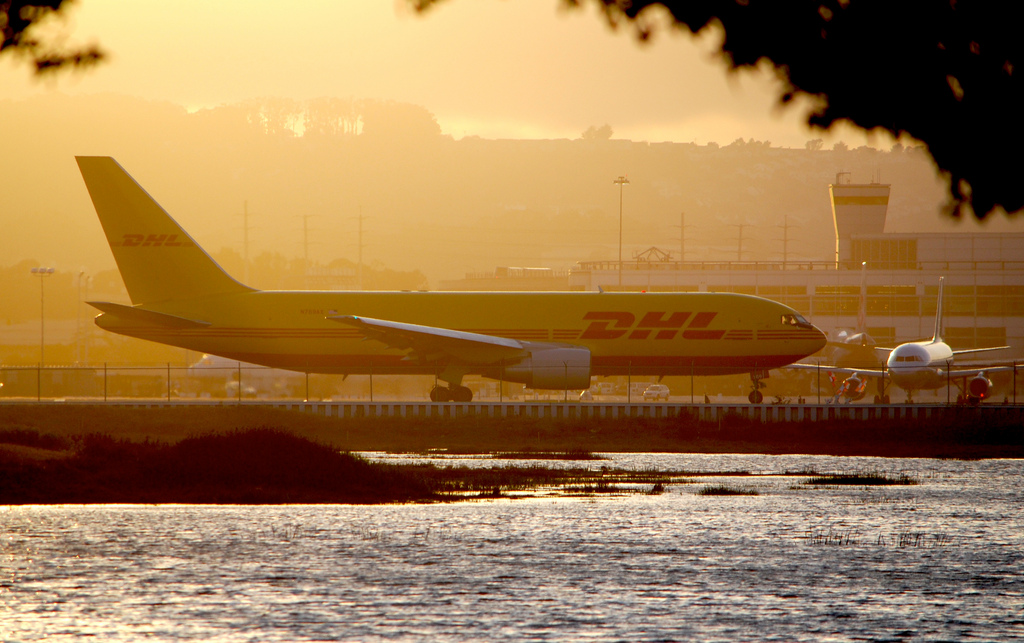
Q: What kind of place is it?
A: It is an airport.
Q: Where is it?
A: This is at the airport.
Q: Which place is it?
A: It is an airport.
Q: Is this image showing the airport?
A: Yes, it is showing the airport.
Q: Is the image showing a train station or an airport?
A: It is showing an airport.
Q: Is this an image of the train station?
A: No, the picture is showing the airport.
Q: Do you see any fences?
A: Yes, there is a fence.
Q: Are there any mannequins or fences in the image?
A: Yes, there is a fence.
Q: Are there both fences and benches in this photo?
A: No, there is a fence but no benches.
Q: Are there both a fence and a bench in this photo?
A: No, there is a fence but no benches.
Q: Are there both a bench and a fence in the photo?
A: No, there is a fence but no benches.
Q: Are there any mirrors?
A: No, there are no mirrors.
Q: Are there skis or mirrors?
A: No, there are no mirrors or skis.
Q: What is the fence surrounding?
A: The fence is surrounding the airport.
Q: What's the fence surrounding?
A: The fence is surrounding the airport.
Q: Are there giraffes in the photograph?
A: No, there are no giraffes.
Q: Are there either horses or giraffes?
A: No, there are no giraffes or horses.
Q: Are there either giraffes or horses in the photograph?
A: No, there are no giraffes or horses.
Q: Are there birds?
A: No, there are no birds.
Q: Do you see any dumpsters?
A: No, there are no dumpsters.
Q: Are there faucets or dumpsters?
A: No, there are no dumpsters or faucets.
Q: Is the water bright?
A: Yes, the water is bright.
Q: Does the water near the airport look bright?
A: Yes, the water is bright.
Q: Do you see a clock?
A: No, there are no clocks.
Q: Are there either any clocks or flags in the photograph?
A: No, there are no clocks or flags.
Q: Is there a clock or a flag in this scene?
A: No, there are no clocks or flags.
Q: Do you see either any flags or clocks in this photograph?
A: No, there are no clocks or flags.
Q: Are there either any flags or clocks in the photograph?
A: No, there are no clocks or flags.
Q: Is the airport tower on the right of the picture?
A: Yes, the tower is on the right of the image.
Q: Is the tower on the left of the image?
A: No, the tower is on the right of the image.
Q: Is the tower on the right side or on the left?
A: The tower is on the right of the image.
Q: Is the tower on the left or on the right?
A: The tower is on the right of the image.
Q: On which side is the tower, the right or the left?
A: The tower is on the right of the image.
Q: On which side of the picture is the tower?
A: The tower is on the right of the image.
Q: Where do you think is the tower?
A: The tower is at the airport.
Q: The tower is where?
A: The tower is at the airport.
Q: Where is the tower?
A: The tower is at the airport.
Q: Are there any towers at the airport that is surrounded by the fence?
A: Yes, there is a tower at the airport.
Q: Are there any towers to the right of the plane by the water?
A: Yes, there is a tower to the right of the plane.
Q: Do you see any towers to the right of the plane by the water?
A: Yes, there is a tower to the right of the plane.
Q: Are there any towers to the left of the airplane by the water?
A: No, the tower is to the right of the airplane.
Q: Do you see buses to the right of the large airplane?
A: No, there is a tower to the right of the airplane.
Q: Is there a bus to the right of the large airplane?
A: No, there is a tower to the right of the airplane.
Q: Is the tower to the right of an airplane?
A: Yes, the tower is to the right of an airplane.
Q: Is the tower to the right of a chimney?
A: No, the tower is to the right of an airplane.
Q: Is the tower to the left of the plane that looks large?
A: No, the tower is to the right of the plane.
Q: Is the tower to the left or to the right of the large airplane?
A: The tower is to the right of the airplane.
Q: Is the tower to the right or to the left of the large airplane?
A: The tower is to the right of the airplane.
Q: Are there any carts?
A: No, there are no carts.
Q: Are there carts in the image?
A: No, there are no carts.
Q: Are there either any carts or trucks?
A: No, there are no carts or trucks.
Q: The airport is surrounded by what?
A: The airport is surrounded by the fence.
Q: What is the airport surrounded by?
A: The airport is surrounded by the fence.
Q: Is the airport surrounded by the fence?
A: Yes, the airport is surrounded by the fence.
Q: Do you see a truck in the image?
A: No, there are no trucks.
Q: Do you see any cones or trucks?
A: No, there are no trucks or cones.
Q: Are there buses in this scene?
A: No, there are no buses.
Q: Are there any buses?
A: No, there are no buses.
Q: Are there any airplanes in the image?
A: Yes, there is an airplane.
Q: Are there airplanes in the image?
A: Yes, there is an airplane.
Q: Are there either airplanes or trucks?
A: Yes, there is an airplane.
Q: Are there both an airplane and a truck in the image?
A: No, there is an airplane but no trucks.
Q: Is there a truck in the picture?
A: No, there are no trucks.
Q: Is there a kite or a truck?
A: No, there are no trucks or kites.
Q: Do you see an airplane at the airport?
A: Yes, there is an airplane at the airport.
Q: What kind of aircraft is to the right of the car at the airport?
A: The aircraft is an airplane.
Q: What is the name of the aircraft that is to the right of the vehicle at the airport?
A: The aircraft is an airplane.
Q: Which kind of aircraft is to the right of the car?
A: The aircraft is an airplane.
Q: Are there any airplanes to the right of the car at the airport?
A: Yes, there is an airplane to the right of the car.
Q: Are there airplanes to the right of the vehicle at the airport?
A: Yes, there is an airplane to the right of the car.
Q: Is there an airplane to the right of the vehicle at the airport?
A: Yes, there is an airplane to the right of the car.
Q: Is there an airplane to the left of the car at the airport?
A: No, the airplane is to the right of the car.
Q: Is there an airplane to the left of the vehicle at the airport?
A: No, the airplane is to the right of the car.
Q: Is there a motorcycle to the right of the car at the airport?
A: No, there is an airplane to the right of the car.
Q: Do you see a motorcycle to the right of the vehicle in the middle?
A: No, there is an airplane to the right of the car.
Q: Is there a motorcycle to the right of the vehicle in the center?
A: No, there is an airplane to the right of the car.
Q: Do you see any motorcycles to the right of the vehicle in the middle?
A: No, there is an airplane to the right of the car.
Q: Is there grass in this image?
A: Yes, there is grass.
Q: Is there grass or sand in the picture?
A: Yes, there is grass.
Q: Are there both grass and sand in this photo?
A: No, there is grass but no sand.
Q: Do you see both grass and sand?
A: No, there is grass but no sand.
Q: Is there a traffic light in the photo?
A: No, there are no traffic lights.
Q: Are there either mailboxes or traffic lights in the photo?
A: No, there are no traffic lights or mailboxes.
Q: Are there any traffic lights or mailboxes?
A: No, there are no traffic lights or mailboxes.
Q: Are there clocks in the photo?
A: No, there are no clocks.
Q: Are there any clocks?
A: No, there are no clocks.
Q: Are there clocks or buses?
A: No, there are no clocks or buses.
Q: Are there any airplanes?
A: Yes, there is an airplane.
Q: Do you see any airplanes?
A: Yes, there is an airplane.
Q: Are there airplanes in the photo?
A: Yes, there is an airplane.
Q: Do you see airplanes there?
A: Yes, there is an airplane.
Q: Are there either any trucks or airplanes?
A: Yes, there is an airplane.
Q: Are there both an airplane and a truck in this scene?
A: No, there is an airplane but no trucks.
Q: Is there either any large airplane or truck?
A: Yes, there is a large airplane.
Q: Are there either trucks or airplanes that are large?
A: Yes, the airplane is large.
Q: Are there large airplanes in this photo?
A: Yes, there is a large airplane.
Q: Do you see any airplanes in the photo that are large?
A: Yes, there is an airplane that is large.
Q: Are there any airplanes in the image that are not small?
A: Yes, there is a large airplane.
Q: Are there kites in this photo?
A: No, there are no kites.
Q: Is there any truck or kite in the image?
A: No, there are no kites or trucks.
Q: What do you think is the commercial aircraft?
A: The aircraft is an airplane.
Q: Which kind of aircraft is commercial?
A: The aircraft is an airplane.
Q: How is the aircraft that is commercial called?
A: The aircraft is an airplane.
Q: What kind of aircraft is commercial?
A: The aircraft is an airplane.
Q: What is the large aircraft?
A: The aircraft is an airplane.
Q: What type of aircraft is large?
A: The aircraft is an airplane.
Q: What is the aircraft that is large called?
A: The aircraft is an airplane.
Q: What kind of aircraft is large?
A: The aircraft is an airplane.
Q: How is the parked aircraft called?
A: The aircraft is an airplane.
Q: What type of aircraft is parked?
A: The aircraft is an airplane.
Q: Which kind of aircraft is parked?
A: The aircraft is an airplane.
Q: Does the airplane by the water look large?
A: Yes, the airplane is large.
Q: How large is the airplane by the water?
A: The plane is large.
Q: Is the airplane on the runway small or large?
A: The airplane is large.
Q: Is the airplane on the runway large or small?
A: The airplane is large.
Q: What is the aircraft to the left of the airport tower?
A: The aircraft is an airplane.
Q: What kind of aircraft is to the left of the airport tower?
A: The aircraft is an airplane.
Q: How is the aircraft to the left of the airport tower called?
A: The aircraft is an airplane.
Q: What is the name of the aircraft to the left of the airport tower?
A: The aircraft is an airplane.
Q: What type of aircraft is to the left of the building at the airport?
A: The aircraft is an airplane.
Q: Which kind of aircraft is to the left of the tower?
A: The aircraft is an airplane.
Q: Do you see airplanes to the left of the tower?
A: Yes, there is an airplane to the left of the tower.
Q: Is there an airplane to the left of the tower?
A: Yes, there is an airplane to the left of the tower.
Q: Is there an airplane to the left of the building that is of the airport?
A: Yes, there is an airplane to the left of the tower.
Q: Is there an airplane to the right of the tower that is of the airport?
A: No, the airplane is to the left of the tower.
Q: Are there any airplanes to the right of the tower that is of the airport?
A: No, the airplane is to the left of the tower.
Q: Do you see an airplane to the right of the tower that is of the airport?
A: No, the airplane is to the left of the tower.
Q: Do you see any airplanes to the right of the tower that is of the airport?
A: No, the airplane is to the left of the tower.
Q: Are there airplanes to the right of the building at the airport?
A: No, the airplane is to the left of the tower.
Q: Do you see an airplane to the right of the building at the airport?
A: No, the airplane is to the left of the tower.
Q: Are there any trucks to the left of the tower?
A: No, there is an airplane to the left of the tower.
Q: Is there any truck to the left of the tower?
A: No, there is an airplane to the left of the tower.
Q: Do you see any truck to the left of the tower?
A: No, there is an airplane to the left of the tower.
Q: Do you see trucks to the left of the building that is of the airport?
A: No, there is an airplane to the left of the tower.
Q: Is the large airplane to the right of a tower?
A: No, the plane is to the left of a tower.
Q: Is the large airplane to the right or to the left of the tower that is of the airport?
A: The plane is to the left of the tower.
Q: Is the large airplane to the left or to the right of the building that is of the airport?
A: The plane is to the left of the tower.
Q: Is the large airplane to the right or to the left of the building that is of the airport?
A: The plane is to the left of the tower.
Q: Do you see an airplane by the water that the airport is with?
A: Yes, there is an airplane by the water.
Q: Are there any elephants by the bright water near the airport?
A: No, there is an airplane by the water.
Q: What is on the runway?
A: The airplane is on the runway.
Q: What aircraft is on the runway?
A: The aircraft is an airplane.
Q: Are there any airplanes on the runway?
A: Yes, there is an airplane on the runway.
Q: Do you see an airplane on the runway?
A: Yes, there is an airplane on the runway.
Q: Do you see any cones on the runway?
A: No, there is an airplane on the runway.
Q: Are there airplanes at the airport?
A: Yes, there is an airplane at the airport.